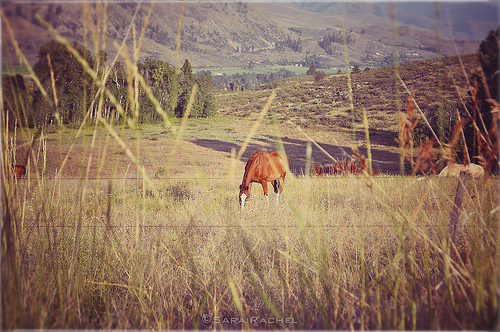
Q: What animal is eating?
A: Horse.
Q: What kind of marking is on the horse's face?
A: Blaze.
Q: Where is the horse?
A: In a field.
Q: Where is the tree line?
A: On the left.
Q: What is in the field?
A: A brown horse.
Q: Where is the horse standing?
A: In the grass.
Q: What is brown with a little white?
A: The horse.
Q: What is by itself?
A: The brown horse.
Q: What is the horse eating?
A: Grass.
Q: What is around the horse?
A: A field of grass.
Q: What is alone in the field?
A: The brown horse.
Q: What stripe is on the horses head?
A: A white stripe.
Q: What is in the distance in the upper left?
A: Green trees.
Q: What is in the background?
A: Mountains.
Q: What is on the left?
A: Row of tall green trees.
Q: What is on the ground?
A: Shadows of trees on the grass.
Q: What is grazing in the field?
A: A horse.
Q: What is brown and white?
A: The horse.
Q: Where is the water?
A: Behind the horse.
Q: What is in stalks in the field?
A: Grain.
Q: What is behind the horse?
A: A hillside.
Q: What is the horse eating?
A: Grass.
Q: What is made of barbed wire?
A: Fence.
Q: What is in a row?
A: Trees.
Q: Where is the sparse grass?
A: On the hillside.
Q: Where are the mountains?
A: Behind the field.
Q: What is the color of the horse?
A: Brown.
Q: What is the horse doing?
A: Eating.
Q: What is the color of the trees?
A: Green.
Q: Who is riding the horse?
A: No one.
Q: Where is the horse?
A: In the field.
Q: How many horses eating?
A: One.